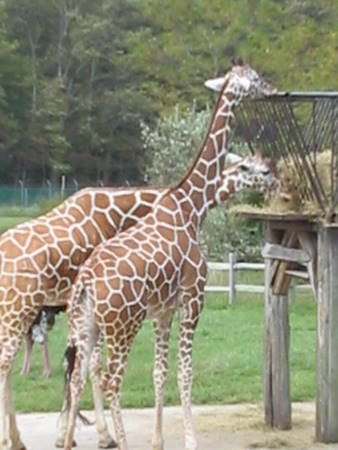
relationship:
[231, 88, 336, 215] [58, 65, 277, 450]
feeding mechanism for animal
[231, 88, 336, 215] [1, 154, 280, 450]
feeding mechanism for animal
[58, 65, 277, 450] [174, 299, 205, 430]
animal has leg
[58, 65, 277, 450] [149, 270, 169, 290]
animal has spot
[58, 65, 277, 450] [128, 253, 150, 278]
animal has spot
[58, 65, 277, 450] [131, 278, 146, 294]
animal has spot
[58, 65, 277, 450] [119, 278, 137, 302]
animal has spot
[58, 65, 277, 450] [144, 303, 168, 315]
animal has spot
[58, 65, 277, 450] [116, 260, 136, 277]
animal has spot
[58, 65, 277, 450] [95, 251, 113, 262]
animal has spot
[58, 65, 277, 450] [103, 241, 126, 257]
animal has spot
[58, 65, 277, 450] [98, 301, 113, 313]
animal has spot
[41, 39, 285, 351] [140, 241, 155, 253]
animal has spot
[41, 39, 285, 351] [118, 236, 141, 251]
animal has spot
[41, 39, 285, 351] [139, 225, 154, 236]
animal has spot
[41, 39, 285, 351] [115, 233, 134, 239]
animal has spot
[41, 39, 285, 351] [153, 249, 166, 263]
animal has spot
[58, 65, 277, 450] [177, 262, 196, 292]
animal has spot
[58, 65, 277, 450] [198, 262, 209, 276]
animal has spot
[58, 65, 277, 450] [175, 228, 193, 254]
animal has spot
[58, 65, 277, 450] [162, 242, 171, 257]
animal has spot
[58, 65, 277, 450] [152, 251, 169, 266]
animal has spot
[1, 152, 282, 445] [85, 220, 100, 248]
animal has spot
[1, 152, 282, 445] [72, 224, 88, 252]
animal has spot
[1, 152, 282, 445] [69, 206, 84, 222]
animal has spot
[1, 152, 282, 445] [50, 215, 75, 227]
animal has spot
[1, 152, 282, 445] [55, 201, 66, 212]
animal has spot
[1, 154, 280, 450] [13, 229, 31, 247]
animal has spot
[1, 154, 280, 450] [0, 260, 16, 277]
animal has spot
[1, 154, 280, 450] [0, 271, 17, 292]
animal has spot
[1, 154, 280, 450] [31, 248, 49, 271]
animal has spot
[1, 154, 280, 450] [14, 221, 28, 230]
animal has spot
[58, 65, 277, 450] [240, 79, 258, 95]
animal has ear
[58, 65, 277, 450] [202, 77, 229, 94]
animal has ear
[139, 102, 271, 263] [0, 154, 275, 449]
tree behind giraffes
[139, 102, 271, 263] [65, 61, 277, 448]
tree behind giraffes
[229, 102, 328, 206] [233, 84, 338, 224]
bars on basket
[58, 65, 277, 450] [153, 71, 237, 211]
animal has brown mane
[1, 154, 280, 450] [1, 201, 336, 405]
animal standing in field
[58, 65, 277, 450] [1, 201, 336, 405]
animal standing in field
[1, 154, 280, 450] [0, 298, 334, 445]
animal in area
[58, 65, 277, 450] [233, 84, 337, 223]
animal eating out of basket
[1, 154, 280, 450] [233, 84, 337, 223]
animal eating out of basket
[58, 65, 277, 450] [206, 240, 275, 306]
animal behind fences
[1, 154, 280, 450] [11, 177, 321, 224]
animal behind fences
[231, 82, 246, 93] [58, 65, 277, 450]
spots are on animal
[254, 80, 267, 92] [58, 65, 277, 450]
spots are on animal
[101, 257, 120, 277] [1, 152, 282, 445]
spots are on animal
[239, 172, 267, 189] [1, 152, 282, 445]
spots are on animal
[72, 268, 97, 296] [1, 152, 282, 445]
spots are on animal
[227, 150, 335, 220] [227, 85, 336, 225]
hay in bin